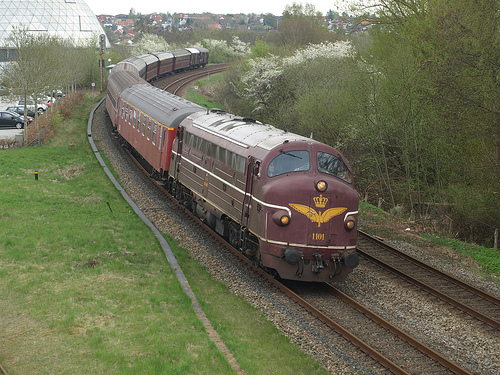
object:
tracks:
[359, 234, 386, 258]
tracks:
[380, 352, 450, 375]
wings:
[322, 206, 349, 223]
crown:
[289, 194, 348, 241]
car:
[166, 108, 360, 282]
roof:
[185, 48, 201, 54]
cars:
[4, 105, 39, 119]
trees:
[436, 166, 500, 230]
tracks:
[410, 271, 448, 280]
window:
[316, 151, 352, 184]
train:
[105, 45, 361, 283]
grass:
[124, 342, 169, 371]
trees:
[395, 143, 467, 182]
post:
[99, 53, 102, 92]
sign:
[289, 180, 348, 240]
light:
[99, 33, 106, 55]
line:
[171, 149, 291, 218]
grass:
[242, 325, 268, 373]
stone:
[389, 290, 453, 335]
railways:
[356, 226, 499, 329]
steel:
[175, 116, 248, 213]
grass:
[0, 273, 58, 303]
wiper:
[278, 148, 302, 158]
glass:
[267, 149, 311, 178]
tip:
[289, 203, 319, 218]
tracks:
[140, 165, 166, 195]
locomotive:
[102, 46, 360, 282]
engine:
[167, 108, 360, 282]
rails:
[272, 281, 470, 375]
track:
[387, 367, 472, 372]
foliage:
[337, 3, 496, 192]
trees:
[386, 0, 495, 51]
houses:
[97, 6, 232, 52]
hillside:
[385, 1, 500, 265]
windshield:
[267, 149, 353, 184]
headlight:
[344, 216, 356, 231]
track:
[286, 281, 334, 298]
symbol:
[288, 194, 347, 241]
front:
[263, 139, 358, 283]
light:
[272, 210, 291, 227]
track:
[462, 284, 500, 334]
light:
[315, 180, 328, 193]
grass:
[3, 351, 133, 372]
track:
[287, 282, 360, 307]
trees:
[0, 16, 94, 129]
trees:
[245, 21, 302, 98]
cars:
[0, 111, 30, 129]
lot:
[0, 89, 66, 129]